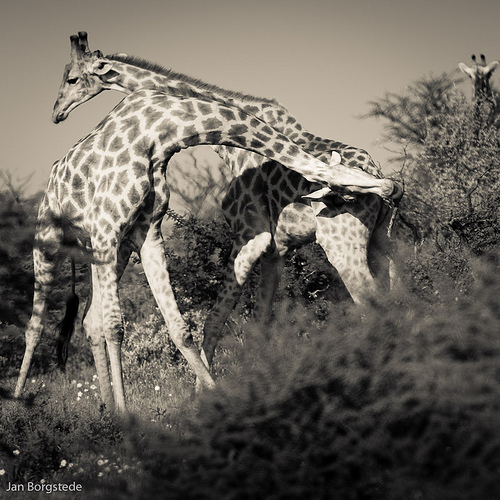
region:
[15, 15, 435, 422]
two giraffes fighting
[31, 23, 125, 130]
the head of a giraffe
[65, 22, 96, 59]
the horns on a giraffe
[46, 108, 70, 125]
the mouth on a giraffe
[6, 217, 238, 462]
the four legs on a giraffe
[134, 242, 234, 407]
a front leg on a giraffe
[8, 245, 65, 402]
a rear leg on a giraffe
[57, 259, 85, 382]
the tail on a giraffe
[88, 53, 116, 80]
the ear on a giraffe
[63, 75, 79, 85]
the eye on a giraffe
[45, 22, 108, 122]
A girraffe's head in black and white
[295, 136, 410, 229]
The underside of a girraffes head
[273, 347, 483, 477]
Blurry black and white bush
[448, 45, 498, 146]
A giraffe poking its head above a tree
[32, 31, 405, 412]
Two girrafes in a field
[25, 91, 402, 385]
A girraffe bending its neck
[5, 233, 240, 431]
Long legs of a giraffe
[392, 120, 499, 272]
A gnarled tree in black and white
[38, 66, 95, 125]
A girraffes face and snout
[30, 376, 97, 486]
Small and bright wild flowers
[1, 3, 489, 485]
the photo is black and white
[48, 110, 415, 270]
the neck is bent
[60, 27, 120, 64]
the horns are two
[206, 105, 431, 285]
the giraffes is scratching the othe giraffe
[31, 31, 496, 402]
the girrafees are three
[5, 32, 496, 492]
the scene was taking in the wild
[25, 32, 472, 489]
the girafee are in the wild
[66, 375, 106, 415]
the flowers are white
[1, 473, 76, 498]
the photographer is jan borgstede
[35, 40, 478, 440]
the giraffes are in africa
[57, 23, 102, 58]
spotted giraffe's horns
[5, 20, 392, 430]
two tall spotted giraffes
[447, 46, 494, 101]
one spotted giraffe hiding in the background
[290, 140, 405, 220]
head of one spotted giraffe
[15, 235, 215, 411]
legs of spotted giraffe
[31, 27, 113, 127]
head of spotted giraffe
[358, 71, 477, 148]
tall dry vegetation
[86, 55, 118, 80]
ear of spotted giraffe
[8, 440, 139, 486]
flowers in field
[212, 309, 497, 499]
short dry vegetation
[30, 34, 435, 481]
Two giraffes in the wild.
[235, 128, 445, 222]
Giraffe eating some leaves.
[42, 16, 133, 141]
Head of the giraffe.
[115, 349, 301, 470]
Shrubs by the giraffe.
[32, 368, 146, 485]
Flowers in the grass.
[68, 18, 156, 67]
Horns on the giraffe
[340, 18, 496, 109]
Giraffe in the background.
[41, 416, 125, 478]
White flowers in the bushes.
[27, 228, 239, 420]
Legs of the giraffe.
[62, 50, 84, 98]
Eye of the giraffe.